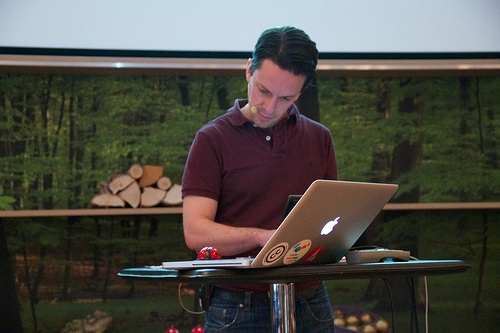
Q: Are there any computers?
A: Yes, there is a computer.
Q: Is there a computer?
A: Yes, there is a computer.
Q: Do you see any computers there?
A: Yes, there is a computer.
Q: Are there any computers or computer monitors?
A: Yes, there is a computer.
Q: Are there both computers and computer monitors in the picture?
A: No, there is a computer but no computer monitors.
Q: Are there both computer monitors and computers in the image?
A: No, there is a computer but no computer monitors.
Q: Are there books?
A: No, there are no books.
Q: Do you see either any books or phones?
A: No, there are no books or phones.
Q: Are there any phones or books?
A: No, there are no books or phones.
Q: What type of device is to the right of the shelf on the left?
A: The device is a computer.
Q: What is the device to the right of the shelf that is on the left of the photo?
A: The device is a computer.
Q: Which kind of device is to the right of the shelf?
A: The device is a computer.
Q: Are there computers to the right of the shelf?
A: Yes, there is a computer to the right of the shelf.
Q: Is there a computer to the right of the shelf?
A: Yes, there is a computer to the right of the shelf.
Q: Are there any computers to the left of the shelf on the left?
A: No, the computer is to the right of the shelf.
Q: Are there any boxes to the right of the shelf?
A: No, there is a computer to the right of the shelf.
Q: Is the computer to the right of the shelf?
A: Yes, the computer is to the right of the shelf.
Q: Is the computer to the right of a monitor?
A: No, the computer is to the right of the shelf.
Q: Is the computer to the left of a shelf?
A: No, the computer is to the right of a shelf.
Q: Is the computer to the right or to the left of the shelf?
A: The computer is to the right of the shelf.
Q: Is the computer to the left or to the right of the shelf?
A: The computer is to the right of the shelf.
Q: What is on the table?
A: The computer is on the table.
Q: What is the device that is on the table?
A: The device is a computer.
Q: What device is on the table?
A: The device is a computer.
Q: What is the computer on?
A: The computer is on the table.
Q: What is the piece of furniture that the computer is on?
A: The piece of furniture is a table.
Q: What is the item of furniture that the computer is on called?
A: The piece of furniture is a table.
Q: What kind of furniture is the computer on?
A: The computer is on the table.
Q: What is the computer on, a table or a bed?
A: The computer is on a table.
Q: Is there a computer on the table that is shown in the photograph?
A: Yes, there is a computer on the table.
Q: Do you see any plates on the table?
A: No, there is a computer on the table.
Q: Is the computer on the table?
A: Yes, the computer is on the table.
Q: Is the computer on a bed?
A: No, the computer is on the table.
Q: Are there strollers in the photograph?
A: No, there are no strollers.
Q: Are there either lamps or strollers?
A: No, there are no strollers or lamps.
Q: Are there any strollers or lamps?
A: No, there are no strollers or lamps.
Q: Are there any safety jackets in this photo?
A: No, there are no safety jackets.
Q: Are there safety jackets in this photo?
A: No, there are no safety jackets.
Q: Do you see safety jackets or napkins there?
A: No, there are no safety jackets or napkins.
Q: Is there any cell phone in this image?
A: No, there are no cell phones.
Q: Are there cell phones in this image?
A: No, there are no cell phones.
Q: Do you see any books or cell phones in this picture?
A: No, there are no cell phones or books.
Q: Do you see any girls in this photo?
A: No, there are no girls.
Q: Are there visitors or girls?
A: No, there are no girls or visitors.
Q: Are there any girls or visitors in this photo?
A: No, there are no girls or visitors.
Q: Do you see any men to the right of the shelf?
A: Yes, there is a man to the right of the shelf.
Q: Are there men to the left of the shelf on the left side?
A: No, the man is to the right of the shelf.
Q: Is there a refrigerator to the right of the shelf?
A: No, there is a man to the right of the shelf.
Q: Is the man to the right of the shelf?
A: Yes, the man is to the right of the shelf.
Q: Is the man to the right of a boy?
A: No, the man is to the right of the shelf.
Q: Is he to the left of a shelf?
A: No, the man is to the right of a shelf.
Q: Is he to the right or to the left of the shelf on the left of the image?
A: The man is to the right of the shelf.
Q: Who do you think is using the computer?
A: The man is using the computer.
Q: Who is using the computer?
A: The man is using the computer.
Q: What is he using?
A: The man is using a computer.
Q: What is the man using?
A: The man is using a computer.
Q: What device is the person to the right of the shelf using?
A: The man is using a computer.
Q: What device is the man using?
A: The man is using a computer.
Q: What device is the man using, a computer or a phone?
A: The man is using a computer.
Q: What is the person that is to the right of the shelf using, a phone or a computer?
A: The man is using a computer.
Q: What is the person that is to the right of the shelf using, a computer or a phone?
A: The man is using a computer.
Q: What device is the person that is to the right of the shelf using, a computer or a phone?
A: The man is using a computer.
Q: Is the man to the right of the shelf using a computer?
A: Yes, the man is using a computer.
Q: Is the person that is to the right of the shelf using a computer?
A: Yes, the man is using a computer.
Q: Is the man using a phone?
A: No, the man is using a computer.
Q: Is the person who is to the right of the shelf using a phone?
A: No, the man is using a computer.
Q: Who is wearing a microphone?
A: The man is wearing a microphone.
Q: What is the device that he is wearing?
A: The device is a microphone.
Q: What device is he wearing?
A: The man is wearing a microphone.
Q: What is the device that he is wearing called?
A: The device is a microphone.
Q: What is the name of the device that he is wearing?
A: The device is a microphone.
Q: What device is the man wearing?
A: The man is wearing a microphone.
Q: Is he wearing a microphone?
A: Yes, the man is wearing a microphone.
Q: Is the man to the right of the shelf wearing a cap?
A: No, the man is wearing a microphone.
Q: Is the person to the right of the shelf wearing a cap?
A: No, the man is wearing a microphone.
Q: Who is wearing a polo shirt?
A: The man is wearing a polo shirt.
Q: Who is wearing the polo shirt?
A: The man is wearing a polo shirt.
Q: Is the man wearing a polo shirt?
A: Yes, the man is wearing a polo shirt.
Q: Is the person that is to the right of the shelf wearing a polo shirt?
A: Yes, the man is wearing a polo shirt.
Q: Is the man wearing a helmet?
A: No, the man is wearing a polo shirt.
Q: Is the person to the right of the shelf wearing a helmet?
A: No, the man is wearing a polo shirt.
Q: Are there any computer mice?
A: Yes, there is a computer mouse.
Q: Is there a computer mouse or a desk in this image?
A: Yes, there is a computer mouse.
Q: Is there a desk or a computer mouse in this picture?
A: Yes, there is a computer mouse.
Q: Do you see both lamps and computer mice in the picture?
A: No, there is a computer mouse but no lamps.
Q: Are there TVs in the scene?
A: No, there are no tvs.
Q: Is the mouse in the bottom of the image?
A: Yes, the mouse is in the bottom of the image.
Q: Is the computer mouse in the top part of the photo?
A: No, the computer mouse is in the bottom of the image.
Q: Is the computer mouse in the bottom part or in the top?
A: The computer mouse is in the bottom of the image.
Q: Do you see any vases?
A: No, there are no vases.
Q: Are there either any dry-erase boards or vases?
A: No, there are no vases or dry-erase boards.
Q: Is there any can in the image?
A: No, there are no cans.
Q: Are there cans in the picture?
A: No, there are no cans.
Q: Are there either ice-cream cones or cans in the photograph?
A: No, there are no cans or ice-cream cones.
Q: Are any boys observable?
A: No, there are no boys.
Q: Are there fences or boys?
A: No, there are no boys or fences.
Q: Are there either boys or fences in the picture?
A: No, there are no boys or fences.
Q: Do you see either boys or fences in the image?
A: No, there are no boys or fences.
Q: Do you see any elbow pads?
A: No, there are no elbow pads.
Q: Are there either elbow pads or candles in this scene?
A: No, there are no elbow pads or candles.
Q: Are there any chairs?
A: No, there are no chairs.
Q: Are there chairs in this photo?
A: No, there are no chairs.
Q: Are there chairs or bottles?
A: No, there are no chairs or bottles.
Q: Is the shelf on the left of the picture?
A: Yes, the shelf is on the left of the image.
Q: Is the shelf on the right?
A: No, the shelf is on the left of the image.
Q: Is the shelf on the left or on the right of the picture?
A: The shelf is on the left of the image.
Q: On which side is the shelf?
A: The shelf is on the left of the image.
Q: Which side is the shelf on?
A: The shelf is on the left of the image.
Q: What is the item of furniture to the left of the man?
A: The piece of furniture is a shelf.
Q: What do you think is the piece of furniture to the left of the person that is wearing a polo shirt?
A: The piece of furniture is a shelf.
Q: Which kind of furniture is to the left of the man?
A: The piece of furniture is a shelf.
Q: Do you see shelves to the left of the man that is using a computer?
A: Yes, there is a shelf to the left of the man.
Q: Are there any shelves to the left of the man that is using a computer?
A: Yes, there is a shelf to the left of the man.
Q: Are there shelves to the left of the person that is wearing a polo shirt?
A: Yes, there is a shelf to the left of the man.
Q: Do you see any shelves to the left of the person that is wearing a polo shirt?
A: Yes, there is a shelf to the left of the man.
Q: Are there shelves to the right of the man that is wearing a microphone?
A: No, the shelf is to the left of the man.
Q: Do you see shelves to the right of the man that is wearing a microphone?
A: No, the shelf is to the left of the man.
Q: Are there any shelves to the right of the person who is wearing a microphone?
A: No, the shelf is to the left of the man.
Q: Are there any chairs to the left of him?
A: No, there is a shelf to the left of the man.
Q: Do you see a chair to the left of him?
A: No, there is a shelf to the left of the man.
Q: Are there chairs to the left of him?
A: No, there is a shelf to the left of the man.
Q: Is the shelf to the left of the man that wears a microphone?
A: Yes, the shelf is to the left of the man.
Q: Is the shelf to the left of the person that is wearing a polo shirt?
A: Yes, the shelf is to the left of the man.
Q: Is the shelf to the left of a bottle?
A: No, the shelf is to the left of the man.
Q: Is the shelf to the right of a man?
A: No, the shelf is to the left of a man.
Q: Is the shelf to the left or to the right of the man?
A: The shelf is to the left of the man.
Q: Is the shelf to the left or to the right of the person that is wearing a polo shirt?
A: The shelf is to the left of the man.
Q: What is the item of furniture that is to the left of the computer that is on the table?
A: The piece of furniture is a shelf.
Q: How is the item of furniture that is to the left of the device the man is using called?
A: The piece of furniture is a shelf.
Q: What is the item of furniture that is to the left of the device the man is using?
A: The piece of furniture is a shelf.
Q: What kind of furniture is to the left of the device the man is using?
A: The piece of furniture is a shelf.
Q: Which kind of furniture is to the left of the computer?
A: The piece of furniture is a shelf.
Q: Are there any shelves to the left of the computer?
A: Yes, there is a shelf to the left of the computer.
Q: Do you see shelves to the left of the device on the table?
A: Yes, there is a shelf to the left of the computer.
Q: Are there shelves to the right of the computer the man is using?
A: No, the shelf is to the left of the computer.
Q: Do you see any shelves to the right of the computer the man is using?
A: No, the shelf is to the left of the computer.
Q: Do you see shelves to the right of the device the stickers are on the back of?
A: No, the shelf is to the left of the computer.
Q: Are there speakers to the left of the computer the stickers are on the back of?
A: No, there is a shelf to the left of the computer.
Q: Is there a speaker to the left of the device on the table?
A: No, there is a shelf to the left of the computer.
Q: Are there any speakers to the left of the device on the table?
A: No, there is a shelf to the left of the computer.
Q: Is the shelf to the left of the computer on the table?
A: Yes, the shelf is to the left of the computer.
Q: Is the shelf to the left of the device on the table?
A: Yes, the shelf is to the left of the computer.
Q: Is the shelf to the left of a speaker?
A: No, the shelf is to the left of the computer.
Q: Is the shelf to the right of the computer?
A: No, the shelf is to the left of the computer.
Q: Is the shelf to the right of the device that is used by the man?
A: No, the shelf is to the left of the computer.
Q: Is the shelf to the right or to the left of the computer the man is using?
A: The shelf is to the left of the computer.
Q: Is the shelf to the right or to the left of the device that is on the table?
A: The shelf is to the left of the computer.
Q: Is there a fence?
A: No, there are no fences.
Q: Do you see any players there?
A: No, there are no players.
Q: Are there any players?
A: No, there are no players.